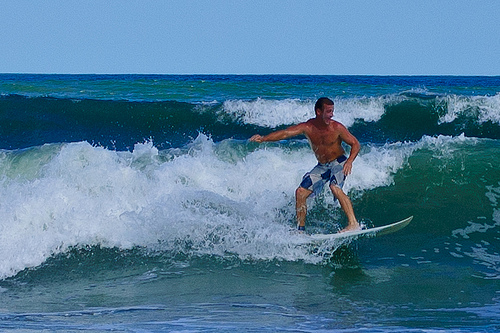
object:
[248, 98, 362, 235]
man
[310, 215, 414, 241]
surfboard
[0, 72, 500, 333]
water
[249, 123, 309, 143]
right arm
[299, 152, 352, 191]
shorts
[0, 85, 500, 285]
waves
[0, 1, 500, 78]
sky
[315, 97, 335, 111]
hair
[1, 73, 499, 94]
calm water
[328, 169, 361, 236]
legs